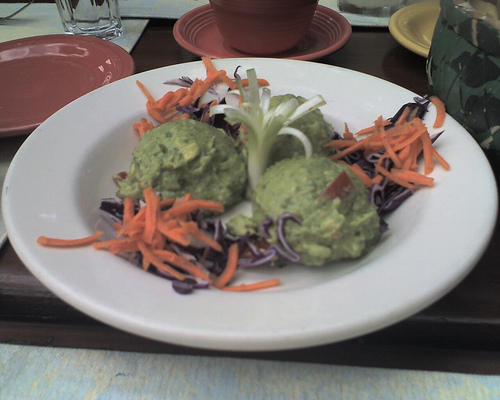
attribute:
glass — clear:
[50, 1, 131, 39]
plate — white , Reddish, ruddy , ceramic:
[19, 33, 489, 365]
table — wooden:
[1, 347, 495, 394]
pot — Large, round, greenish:
[429, 4, 499, 147]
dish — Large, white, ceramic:
[6, 39, 492, 349]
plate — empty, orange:
[30, 43, 169, 163]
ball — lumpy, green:
[242, 150, 387, 270]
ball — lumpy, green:
[115, 110, 249, 212]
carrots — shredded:
[125, 195, 199, 270]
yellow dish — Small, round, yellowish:
[390, 1, 440, 52]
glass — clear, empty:
[55, 0, 125, 43]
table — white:
[34, 366, 122, 398]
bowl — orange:
[206, 1, 321, 56]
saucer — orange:
[171, 1, 350, 61]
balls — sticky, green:
[120, 109, 244, 226]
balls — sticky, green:
[246, 142, 387, 272]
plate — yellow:
[383, 4, 457, 48]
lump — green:
[239, 147, 390, 276]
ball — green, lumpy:
[110, 110, 252, 221]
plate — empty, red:
[0, 25, 139, 138]